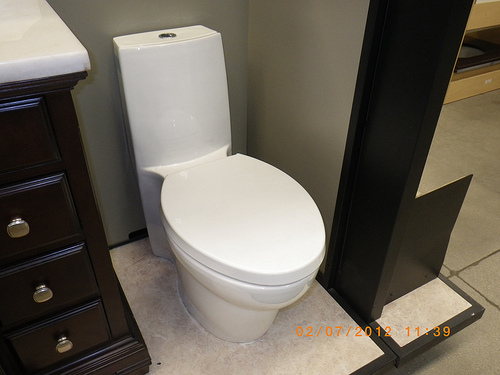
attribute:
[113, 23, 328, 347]
toilet — white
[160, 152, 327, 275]
lid — closed, white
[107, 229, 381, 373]
floor — white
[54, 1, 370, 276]
wall — white, gray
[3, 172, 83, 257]
drawer — brown, black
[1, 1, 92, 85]
counter — white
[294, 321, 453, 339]
date — orange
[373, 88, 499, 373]
floor — tile